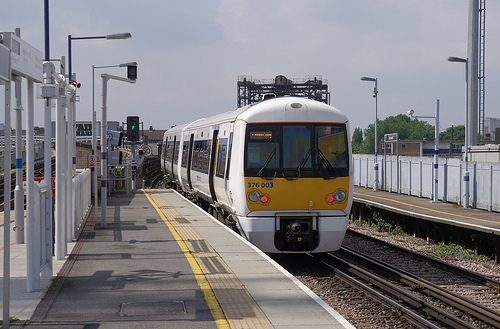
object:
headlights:
[249, 190, 348, 202]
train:
[159, 96, 356, 254]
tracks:
[315, 245, 500, 329]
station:
[0, 21, 300, 328]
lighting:
[105, 31, 136, 41]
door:
[209, 129, 220, 204]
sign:
[250, 132, 273, 139]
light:
[126, 115, 140, 142]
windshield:
[245, 123, 352, 176]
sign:
[384, 133, 398, 141]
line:
[140, 188, 215, 327]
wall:
[351, 153, 499, 213]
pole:
[132, 143, 135, 190]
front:
[245, 96, 356, 254]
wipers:
[258, 146, 339, 180]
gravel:
[322, 261, 417, 328]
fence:
[351, 154, 500, 214]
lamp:
[406, 109, 416, 115]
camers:
[127, 65, 138, 80]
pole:
[99, 77, 108, 229]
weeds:
[367, 211, 410, 237]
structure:
[236, 73, 332, 109]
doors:
[165, 130, 224, 204]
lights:
[247, 191, 348, 203]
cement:
[77, 230, 208, 328]